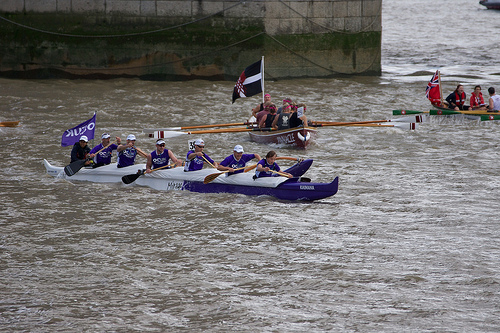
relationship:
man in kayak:
[221, 146, 259, 174] [50, 137, 331, 208]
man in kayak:
[184, 137, 215, 171] [50, 137, 331, 208]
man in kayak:
[146, 138, 184, 175] [50, 137, 331, 208]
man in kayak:
[117, 133, 148, 165] [50, 137, 331, 208]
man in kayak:
[94, 134, 117, 164] [50, 137, 331, 208]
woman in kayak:
[254, 149, 286, 177] [50, 137, 331, 208]